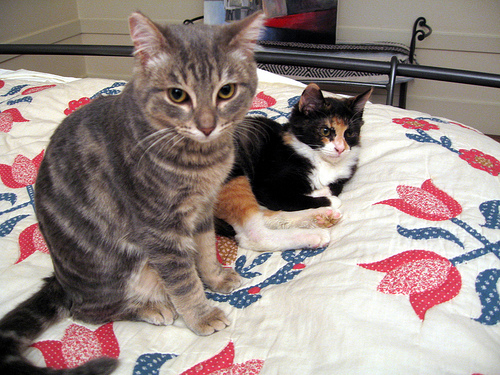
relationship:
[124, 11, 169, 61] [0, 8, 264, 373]
ear of a cat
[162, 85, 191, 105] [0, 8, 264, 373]
eye of a cat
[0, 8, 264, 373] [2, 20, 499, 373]
cat sitting on blanket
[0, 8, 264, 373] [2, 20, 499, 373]
cat on top of blanket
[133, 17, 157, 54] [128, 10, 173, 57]
hair in ear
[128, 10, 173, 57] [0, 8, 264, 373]
ear of cat